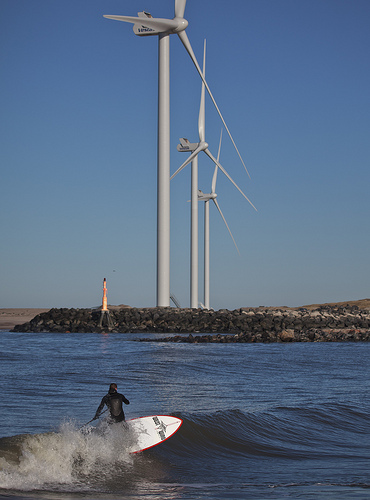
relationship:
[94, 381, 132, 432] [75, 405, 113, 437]
surfer with paddle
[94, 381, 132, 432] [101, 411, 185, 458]
surfer on board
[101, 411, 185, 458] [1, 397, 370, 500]
board on wave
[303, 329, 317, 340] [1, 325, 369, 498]
rock along water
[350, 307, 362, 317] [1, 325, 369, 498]
rock along water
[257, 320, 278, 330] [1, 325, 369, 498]
rock along water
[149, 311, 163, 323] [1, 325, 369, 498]
rock along water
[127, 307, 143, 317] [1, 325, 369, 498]
rock along water